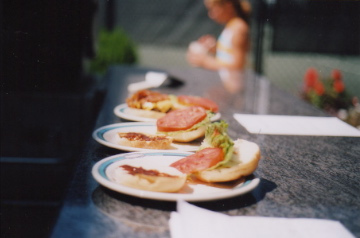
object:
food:
[112, 88, 260, 193]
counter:
[51, 68, 359, 236]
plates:
[114, 100, 222, 124]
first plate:
[90, 149, 261, 203]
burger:
[109, 161, 187, 191]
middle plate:
[91, 120, 229, 152]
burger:
[114, 129, 172, 149]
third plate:
[113, 94, 222, 122]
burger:
[157, 106, 222, 143]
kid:
[186, 0, 251, 96]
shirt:
[217, 18, 250, 79]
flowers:
[304, 67, 324, 94]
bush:
[91, 26, 141, 72]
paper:
[232, 113, 359, 138]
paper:
[168, 197, 356, 238]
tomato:
[155, 107, 207, 132]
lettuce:
[197, 118, 235, 170]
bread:
[190, 139, 260, 183]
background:
[0, 1, 359, 137]